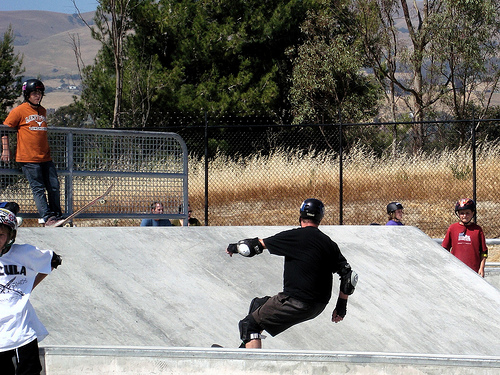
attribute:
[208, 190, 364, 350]
skater — black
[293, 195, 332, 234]
helmets — black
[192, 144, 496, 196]
grass area — brown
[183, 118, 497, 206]
fence — metal, black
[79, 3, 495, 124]
trees — green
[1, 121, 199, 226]
fence — metal